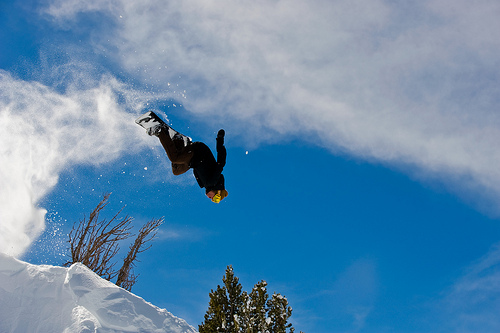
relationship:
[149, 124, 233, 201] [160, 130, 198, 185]
person wearing pants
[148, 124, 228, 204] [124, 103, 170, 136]
person doing trick on snow board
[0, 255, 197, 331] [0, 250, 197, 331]
ground covered in snow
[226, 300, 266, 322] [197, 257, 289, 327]
leaves on tree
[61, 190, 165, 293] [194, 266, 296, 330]
branches near tree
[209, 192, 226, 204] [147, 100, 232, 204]
goggles on snowboarder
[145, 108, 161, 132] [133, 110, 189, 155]
snow on snowboard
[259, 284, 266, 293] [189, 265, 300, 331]
snow on tree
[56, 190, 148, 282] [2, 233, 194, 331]
branches on top of hill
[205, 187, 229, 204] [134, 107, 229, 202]
head of a person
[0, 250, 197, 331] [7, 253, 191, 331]
snow on hill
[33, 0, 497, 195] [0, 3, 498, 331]
clouds in sky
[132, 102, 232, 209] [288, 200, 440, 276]
snowboarder in air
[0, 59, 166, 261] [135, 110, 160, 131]
snow coming off snowboarder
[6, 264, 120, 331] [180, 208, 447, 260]
snow in air